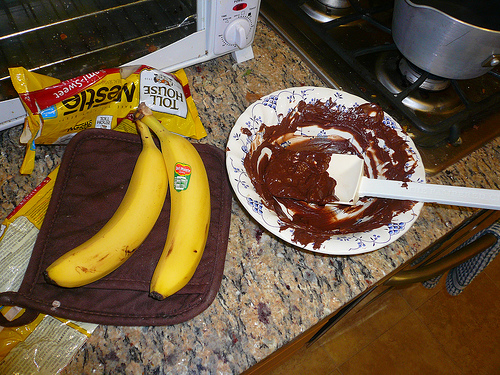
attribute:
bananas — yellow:
[133, 107, 215, 300]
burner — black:
[361, 32, 481, 132]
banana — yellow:
[142, 107, 212, 296]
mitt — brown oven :
[59, 149, 117, 220]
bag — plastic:
[4, 64, 203, 151]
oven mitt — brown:
[27, 98, 254, 368]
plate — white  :
[223, 72, 436, 256]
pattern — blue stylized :
[261, 92, 281, 121]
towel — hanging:
[425, 227, 499, 295]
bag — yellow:
[11, 67, 203, 146]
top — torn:
[2, 103, 45, 175]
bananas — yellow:
[54, 107, 205, 327]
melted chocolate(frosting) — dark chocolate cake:
[247, 100, 412, 242]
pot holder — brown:
[1, 121, 231, 331]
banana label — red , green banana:
[171, 160, 193, 196]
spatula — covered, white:
[260, 142, 499, 216]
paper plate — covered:
[230, 75, 426, 262]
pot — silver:
[371, 0, 487, 86]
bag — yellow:
[4, 63, 211, 146]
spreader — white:
[269, 145, 497, 219]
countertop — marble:
[348, 243, 425, 276]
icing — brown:
[263, 119, 336, 229]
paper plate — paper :
[222, 79, 427, 254]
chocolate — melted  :
[248, 109, 415, 247]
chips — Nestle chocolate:
[14, 66, 194, 146]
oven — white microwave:
[3, 3, 249, 138]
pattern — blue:
[246, 188, 266, 219]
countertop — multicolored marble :
[3, 15, 498, 369]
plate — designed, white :
[223, 83, 429, 258]